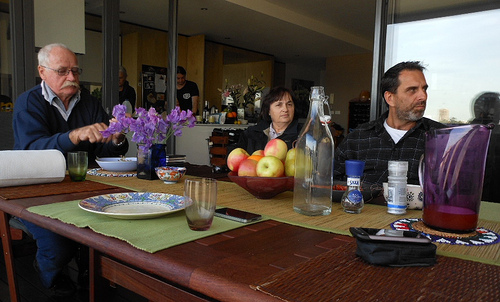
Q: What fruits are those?
A: Apples.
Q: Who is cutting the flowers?
A: The old man.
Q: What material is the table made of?
A: Wood.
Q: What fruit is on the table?
A: Apples.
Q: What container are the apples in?
A: A bowl.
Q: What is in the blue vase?
A: Flowers.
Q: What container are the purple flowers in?
A: A vase.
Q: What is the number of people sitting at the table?
A: Three.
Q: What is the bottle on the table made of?
A: Glass.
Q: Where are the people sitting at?
A: The table.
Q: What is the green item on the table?
A: Placemat.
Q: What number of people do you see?
A: Five people.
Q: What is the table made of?
A: Wood.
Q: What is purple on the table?
A: Flowers.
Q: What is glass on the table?
A: A pitcher of juice.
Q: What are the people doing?
A: Sitting at the table.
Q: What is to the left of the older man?
A: A roll of paper towels.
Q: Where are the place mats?
A: Under the plates.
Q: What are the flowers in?
A: A square glass vase.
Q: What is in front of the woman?
A: A bowl of apples.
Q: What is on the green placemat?
A: A cell phone.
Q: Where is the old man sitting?
A: On the left.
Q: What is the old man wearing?
A: A blue sweater.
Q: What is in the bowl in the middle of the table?
A: Apples.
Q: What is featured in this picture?
A: Three people sitting at a table.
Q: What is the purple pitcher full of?
A: Juice.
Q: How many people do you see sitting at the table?
A: 3.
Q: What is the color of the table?
A: Brown.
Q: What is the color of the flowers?
A: Purple.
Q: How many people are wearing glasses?
A: One.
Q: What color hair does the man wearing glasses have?
A: Grey.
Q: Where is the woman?
A: In between the two men.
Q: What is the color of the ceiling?
A: White.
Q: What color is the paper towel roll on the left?
A: White.